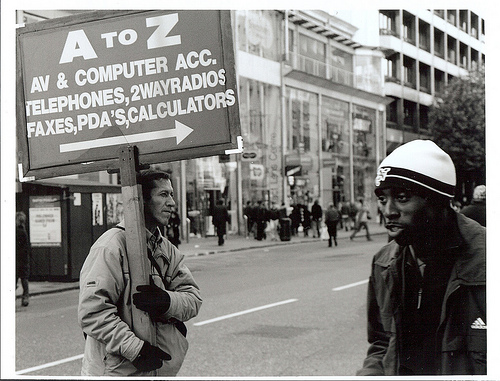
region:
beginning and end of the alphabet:
[57, 10, 189, 65]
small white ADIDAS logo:
[468, 314, 486, 334]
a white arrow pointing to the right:
[55, 118, 195, 156]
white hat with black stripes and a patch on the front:
[371, 137, 458, 202]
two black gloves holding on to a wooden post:
[130, 272, 173, 374]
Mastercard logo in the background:
[237, 148, 257, 159]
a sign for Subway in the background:
[280, 160, 300, 175]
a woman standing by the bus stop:
[12, 209, 32, 308]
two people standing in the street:
[320, 199, 372, 250]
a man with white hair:
[470, 182, 485, 205]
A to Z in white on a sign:
[45, 5, 200, 54]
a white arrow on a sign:
[25, 119, 233, 154]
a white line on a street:
[214, 287, 302, 336]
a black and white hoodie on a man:
[385, 140, 450, 195]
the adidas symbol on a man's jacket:
[465, 307, 487, 338]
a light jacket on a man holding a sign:
[62, 226, 214, 373]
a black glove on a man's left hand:
[134, 280, 174, 316]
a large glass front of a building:
[242, 19, 389, 193]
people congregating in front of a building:
[230, 191, 353, 246]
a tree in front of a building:
[433, 69, 496, 164]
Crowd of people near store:
[203, 189, 330, 252]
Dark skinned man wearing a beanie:
[345, 103, 463, 268]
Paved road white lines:
[189, 253, 376, 330]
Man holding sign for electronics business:
[13, 4, 249, 370]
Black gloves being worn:
[100, 264, 185, 369]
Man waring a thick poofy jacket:
[72, 151, 220, 374]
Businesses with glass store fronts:
[240, 77, 395, 240]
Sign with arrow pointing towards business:
[17, 23, 242, 156]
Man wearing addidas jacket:
[350, 119, 497, 379]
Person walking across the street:
[342, 193, 377, 250]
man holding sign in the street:
[9, 12, 263, 379]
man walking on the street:
[328, 120, 493, 377]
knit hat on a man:
[354, 132, 474, 209]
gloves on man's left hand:
[129, 268, 173, 325]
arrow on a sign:
[50, 115, 207, 155]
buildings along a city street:
[254, 20, 427, 143]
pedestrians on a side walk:
[209, 185, 369, 255]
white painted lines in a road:
[216, 277, 368, 321]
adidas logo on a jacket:
[464, 307, 491, 338]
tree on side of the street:
[431, 60, 486, 207]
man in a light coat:
[56, 167, 206, 372]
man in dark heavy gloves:
[75, 166, 204, 376]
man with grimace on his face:
[75, 168, 202, 375]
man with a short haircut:
[72, 163, 204, 372]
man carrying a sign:
[77, 167, 200, 375]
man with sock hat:
[352, 137, 485, 375]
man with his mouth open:
[353, 135, 488, 377]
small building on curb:
[17, 172, 121, 282]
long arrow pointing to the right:
[51, 117, 198, 158]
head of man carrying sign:
[137, 167, 176, 229]